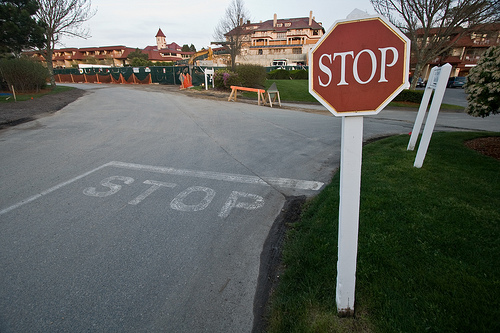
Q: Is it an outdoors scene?
A: Yes, it is outdoors.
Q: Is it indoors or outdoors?
A: It is outdoors.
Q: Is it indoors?
A: No, it is outdoors.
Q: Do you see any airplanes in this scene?
A: No, there are no airplanes.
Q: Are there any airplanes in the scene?
A: No, there are no airplanes.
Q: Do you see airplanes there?
A: No, there are no airplanes.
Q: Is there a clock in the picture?
A: No, there are no clocks.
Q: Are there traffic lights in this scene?
A: No, there are no traffic lights.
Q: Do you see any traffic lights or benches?
A: No, there are no traffic lights or benches.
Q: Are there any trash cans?
A: No, there are no trash cans.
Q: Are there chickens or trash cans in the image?
A: No, there are no trash cans or chickens.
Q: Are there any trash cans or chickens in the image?
A: No, there are no trash cans or chickens.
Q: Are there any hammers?
A: No, there are no hammers.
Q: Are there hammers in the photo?
A: No, there are no hammers.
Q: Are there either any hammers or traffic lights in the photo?
A: No, there are no hammers or traffic lights.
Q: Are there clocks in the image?
A: No, there are no clocks.